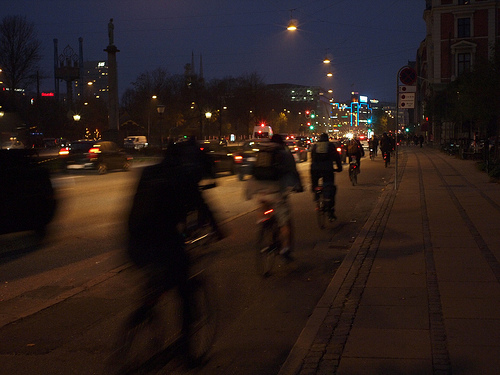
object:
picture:
[0, 0, 499, 374]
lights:
[283, 26, 299, 32]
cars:
[0, 141, 59, 257]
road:
[0, 146, 390, 375]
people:
[345, 137, 363, 177]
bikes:
[252, 181, 305, 279]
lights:
[322, 71, 334, 79]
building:
[258, 82, 333, 134]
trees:
[116, 68, 269, 141]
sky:
[0, 2, 428, 106]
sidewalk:
[381, 123, 498, 373]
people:
[114, 137, 234, 357]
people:
[241, 133, 306, 259]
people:
[303, 131, 343, 211]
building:
[335, 92, 382, 131]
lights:
[356, 112, 362, 116]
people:
[416, 134, 423, 149]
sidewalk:
[280, 142, 500, 374]